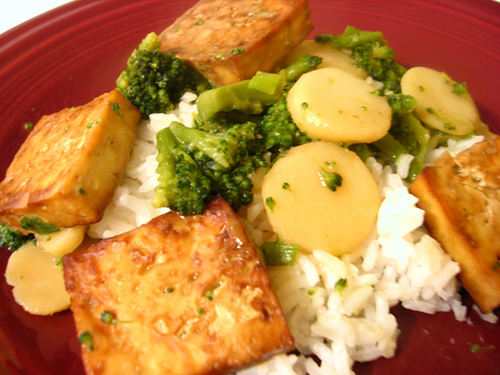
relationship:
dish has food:
[0, 0, 499, 375] [0, 0, 499, 373]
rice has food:
[75, 56, 487, 372] [0, 0, 499, 373]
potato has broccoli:
[258, 138, 381, 261] [315, 162, 344, 192]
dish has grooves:
[0, 0, 499, 375] [0, 0, 189, 124]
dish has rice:
[0, 0, 499, 375] [250, 154, 467, 374]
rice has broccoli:
[75, 56, 487, 372] [144, 78, 263, 217]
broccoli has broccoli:
[115, 29, 211, 116] [115, 30, 211, 116]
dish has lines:
[0, 0, 499, 375] [2, 0, 175, 130]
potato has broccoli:
[259, 138, 381, 261] [320, 168, 344, 191]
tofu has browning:
[61, 193, 297, 373] [215, 168, 295, 347]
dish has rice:
[0, 0, 499, 375] [75, 56, 487, 372]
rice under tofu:
[75, 56, 487, 372] [2, 0, 498, 373]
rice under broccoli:
[75, 56, 485, 367] [116, 15, 443, 273]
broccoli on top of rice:
[115, 30, 211, 116] [75, 56, 485, 367]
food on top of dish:
[0, 0, 499, 373] [0, 0, 499, 375]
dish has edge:
[0, 0, 499, 375] [3, 0, 82, 47]